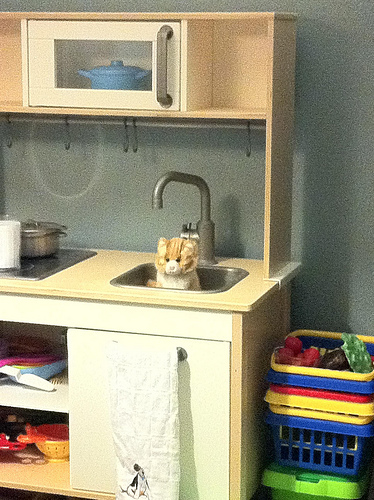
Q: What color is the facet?
A: Gray.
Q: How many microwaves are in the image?
A: One.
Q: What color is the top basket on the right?
A: Yellow.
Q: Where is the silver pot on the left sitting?
A: On the stove.